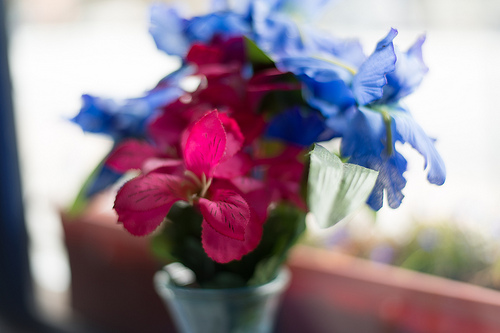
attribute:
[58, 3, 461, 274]
flowers — cute